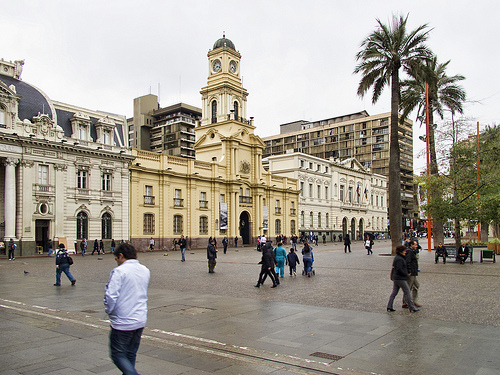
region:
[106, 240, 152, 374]
This is a person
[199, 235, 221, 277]
This is a person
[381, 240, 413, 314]
This is a person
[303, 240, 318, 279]
This is a person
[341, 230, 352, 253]
This is a person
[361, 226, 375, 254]
This is a person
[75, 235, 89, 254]
This is a person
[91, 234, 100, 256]
This is a person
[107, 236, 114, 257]
This is a person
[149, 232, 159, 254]
This is a person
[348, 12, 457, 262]
large palm trees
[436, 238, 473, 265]
people sitting on street bench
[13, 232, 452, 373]
people walking in city square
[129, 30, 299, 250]
stone building painted yellow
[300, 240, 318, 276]
woman walking and pushing stroller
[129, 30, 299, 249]
building with bell tower and clock faces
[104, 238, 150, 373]
man wearing blue jeans and white jacket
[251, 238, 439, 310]
people wearing pants and jackets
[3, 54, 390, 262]
row of stone buildings opening on square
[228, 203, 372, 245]
arched stone doorways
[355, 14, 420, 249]
a tall palm tree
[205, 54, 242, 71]
a clock on top of a building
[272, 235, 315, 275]
a family is walking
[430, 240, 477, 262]
two people sitting on a bench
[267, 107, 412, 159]
a residential building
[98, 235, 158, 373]
a man walking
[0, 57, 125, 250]
an old building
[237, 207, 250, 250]
entrance to an old building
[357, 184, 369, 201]
a flag is attached to a pole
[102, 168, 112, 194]
a window on the first floor of a building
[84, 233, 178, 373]
this is a person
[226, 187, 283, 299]
this is a person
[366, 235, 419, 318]
this is a person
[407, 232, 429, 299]
this is a person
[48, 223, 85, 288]
this is a person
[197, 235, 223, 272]
this is a person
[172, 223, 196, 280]
this is a person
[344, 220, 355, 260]
this is a person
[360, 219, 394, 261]
this is a person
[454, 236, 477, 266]
this is a person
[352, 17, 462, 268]
Green and brown palm trees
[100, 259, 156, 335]
White shirt on man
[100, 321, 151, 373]
Blue jeans on man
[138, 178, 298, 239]
Windows on beige building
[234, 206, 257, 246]
Door on beige building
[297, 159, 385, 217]
Windows on white building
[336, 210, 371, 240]
Doors on white building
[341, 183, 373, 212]
Flags on white building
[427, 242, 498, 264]
Green benches on ground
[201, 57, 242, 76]
Clock faces on tower